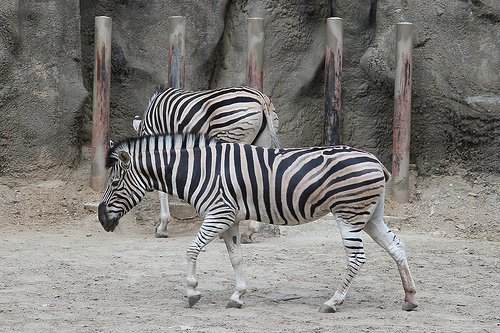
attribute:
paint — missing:
[326, 39, 364, 113]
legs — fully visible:
[178, 206, 253, 314]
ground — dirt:
[436, 145, 468, 172]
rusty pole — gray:
[394, 24, 415, 205]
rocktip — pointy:
[334, 19, 407, 94]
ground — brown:
[3, 224, 494, 331]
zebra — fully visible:
[64, 117, 414, 299]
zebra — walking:
[112, 112, 412, 283]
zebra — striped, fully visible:
[86, 136, 426, 319]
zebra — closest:
[134, 81, 284, 241]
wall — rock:
[1, 0, 499, 189]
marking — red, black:
[92, 43, 112, 154]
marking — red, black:
[165, 28, 185, 87]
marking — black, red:
[325, 47, 345, 151]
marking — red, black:
[390, 50, 417, 180]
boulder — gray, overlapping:
[1, 4, 90, 176]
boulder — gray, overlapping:
[82, 0, 226, 157]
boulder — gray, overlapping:
[210, 9, 372, 147]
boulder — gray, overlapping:
[360, 5, 496, 165]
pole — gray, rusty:
[386, 18, 418, 207]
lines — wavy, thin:
[224, 122, 252, 139]